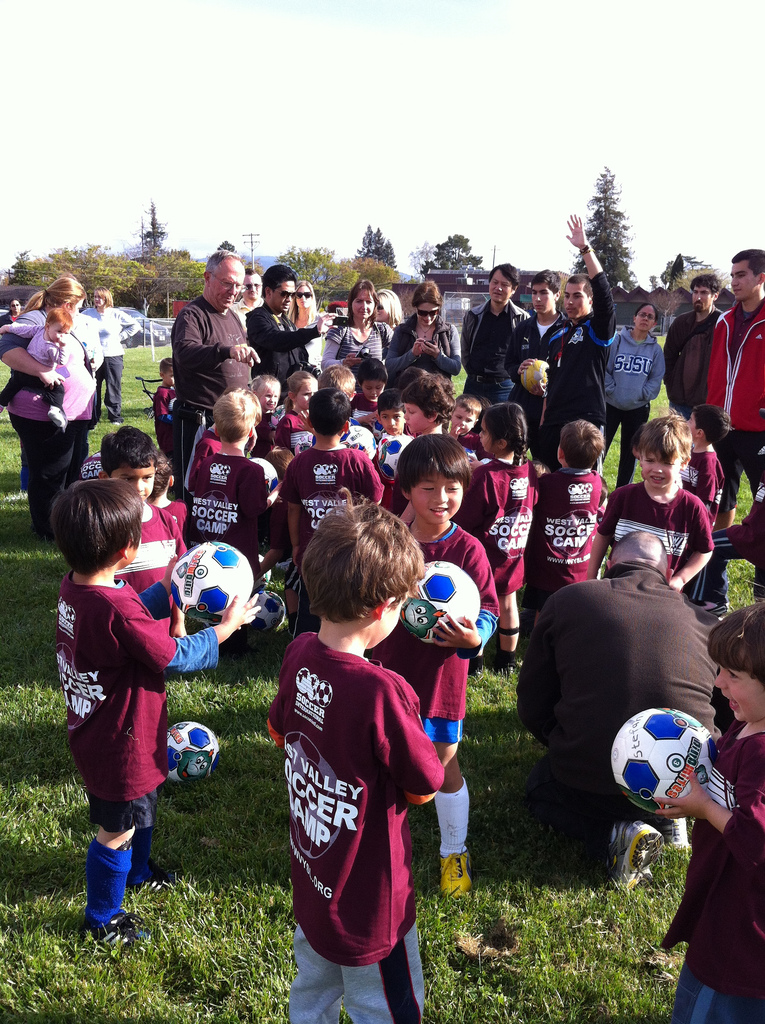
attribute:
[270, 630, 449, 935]
shirts — maroon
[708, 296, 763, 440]
coat — red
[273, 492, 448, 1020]
child — soccer jersey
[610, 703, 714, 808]
ball — soccer ball, blue, white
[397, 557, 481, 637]
ball — soccer ball, blue, white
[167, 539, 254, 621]
ball — soccer ball, blue, white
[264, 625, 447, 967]
jersey — maroon